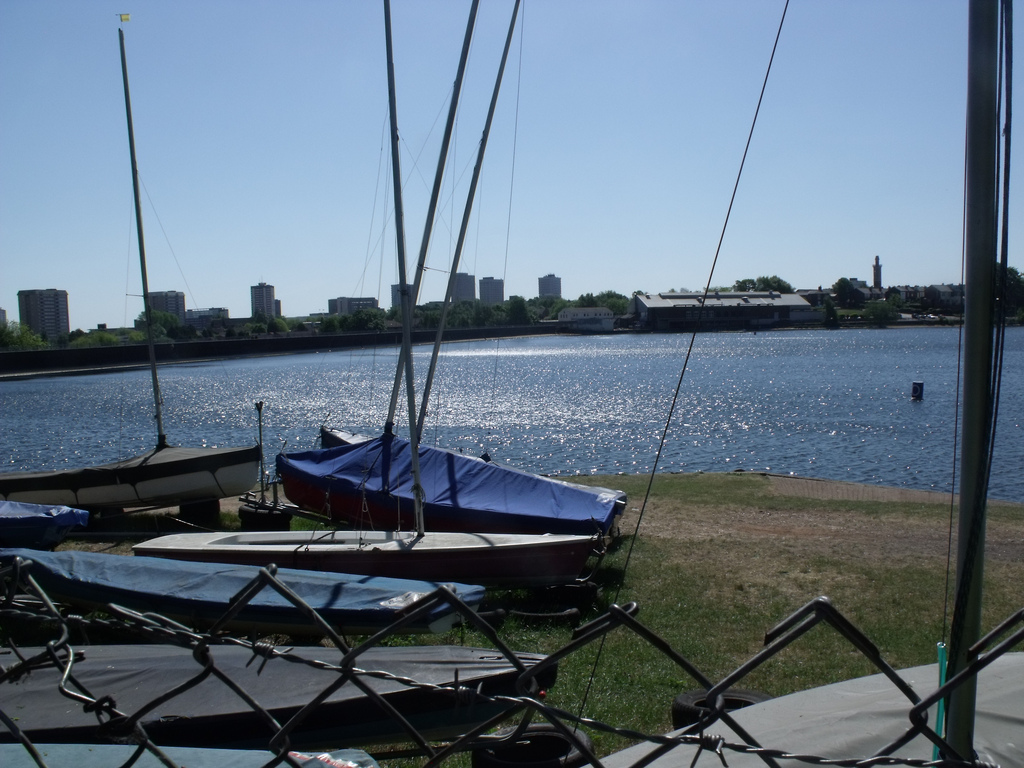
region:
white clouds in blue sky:
[216, 113, 347, 215]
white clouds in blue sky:
[693, 83, 836, 188]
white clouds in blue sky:
[406, 63, 528, 112]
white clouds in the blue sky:
[792, 105, 888, 148]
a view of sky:
[562, 89, 652, 166]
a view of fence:
[130, 511, 740, 765]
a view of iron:
[629, 606, 876, 746]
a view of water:
[597, 334, 797, 412]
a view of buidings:
[70, 237, 728, 354]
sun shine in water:
[268, 326, 649, 504]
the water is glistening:
[3, 325, 1021, 497]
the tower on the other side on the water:
[869, 256, 885, 294]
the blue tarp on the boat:
[277, 433, 628, 531]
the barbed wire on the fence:
[0, 598, 977, 766]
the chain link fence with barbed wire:
[2, 551, 1020, 764]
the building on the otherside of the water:
[623, 291, 814, 334]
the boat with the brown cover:
[0, 434, 266, 517]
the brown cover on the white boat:
[0, 443, 260, 492]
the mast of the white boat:
[114, 29, 166, 450]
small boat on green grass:
[271, 431, 622, 534]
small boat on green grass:
[22, 436, 256, 506]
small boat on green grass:
[182, 528, 578, 568]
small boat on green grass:
[29, 616, 539, 706]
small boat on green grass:
[15, 728, 322, 763]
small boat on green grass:
[609, 610, 996, 759]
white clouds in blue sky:
[610, 69, 680, 146]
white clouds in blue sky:
[833, 70, 890, 156]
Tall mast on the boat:
[68, 35, 224, 446]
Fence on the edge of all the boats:
[40, 563, 930, 763]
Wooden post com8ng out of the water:
[903, 365, 930, 413]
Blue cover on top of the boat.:
[288, 370, 622, 595]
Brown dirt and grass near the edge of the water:
[625, 478, 1009, 603]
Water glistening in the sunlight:
[269, 358, 652, 470]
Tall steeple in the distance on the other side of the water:
[860, 250, 892, 298]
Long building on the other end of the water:
[619, 279, 844, 353]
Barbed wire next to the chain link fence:
[62, 636, 632, 741]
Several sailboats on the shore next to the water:
[62, 361, 689, 751]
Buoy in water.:
[905, 372, 926, 405]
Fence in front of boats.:
[1, 557, 1020, 767]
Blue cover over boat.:
[276, 428, 625, 527]